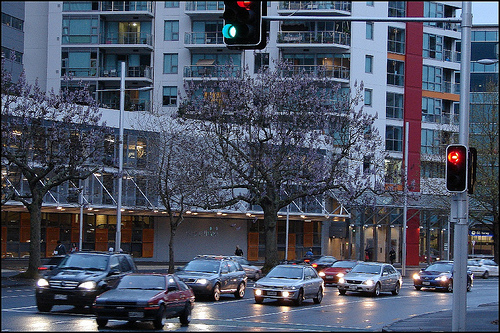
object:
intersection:
[0, 0, 500, 333]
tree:
[0, 42, 119, 282]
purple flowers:
[7, 47, 19, 63]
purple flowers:
[81, 80, 91, 93]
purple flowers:
[46, 125, 61, 141]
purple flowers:
[95, 120, 107, 131]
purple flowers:
[11, 98, 26, 115]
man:
[234, 245, 243, 256]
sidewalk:
[137, 265, 169, 270]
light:
[444, 144, 469, 193]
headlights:
[338, 277, 346, 284]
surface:
[0, 273, 497, 333]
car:
[336, 261, 402, 298]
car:
[91, 273, 196, 330]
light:
[135, 299, 148, 306]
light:
[95, 297, 108, 304]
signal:
[444, 143, 467, 195]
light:
[221, 0, 269, 51]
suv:
[32, 250, 137, 313]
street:
[0, 260, 497, 333]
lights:
[337, 277, 373, 287]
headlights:
[254, 288, 262, 296]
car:
[168, 255, 249, 302]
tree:
[157, 58, 384, 274]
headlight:
[281, 291, 290, 299]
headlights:
[34, 278, 50, 288]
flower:
[84, 95, 94, 105]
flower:
[33, 77, 42, 94]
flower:
[94, 111, 102, 122]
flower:
[14, 96, 20, 107]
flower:
[60, 112, 74, 125]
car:
[318, 259, 359, 287]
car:
[252, 263, 326, 305]